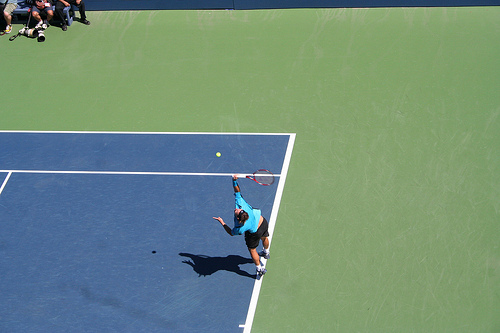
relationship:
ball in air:
[215, 151, 222, 160] [0, 1, 499, 332]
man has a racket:
[215, 177, 271, 279] [234, 168, 274, 189]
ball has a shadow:
[215, 151, 222, 160] [153, 249, 159, 254]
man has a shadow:
[215, 177, 271, 279] [178, 251, 261, 280]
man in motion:
[215, 177, 271, 279] [210, 174, 293, 280]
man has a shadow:
[215, 177, 271, 279] [153, 249, 159, 254]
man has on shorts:
[215, 177, 271, 279] [245, 217, 270, 249]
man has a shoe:
[215, 177, 271, 279] [256, 265, 265, 281]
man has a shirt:
[215, 177, 271, 279] [232, 195, 262, 235]